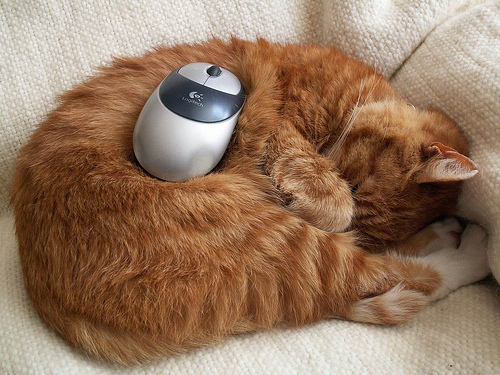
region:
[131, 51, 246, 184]
Computer mouse on cat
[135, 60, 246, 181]
Gray and black mouse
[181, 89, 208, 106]
Writing on a mouse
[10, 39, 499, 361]
Cat lying on couch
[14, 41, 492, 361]
Brown cat on couch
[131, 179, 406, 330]
Stripes on body's cat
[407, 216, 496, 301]
White fur on cat's legs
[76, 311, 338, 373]
Brown tail of a cat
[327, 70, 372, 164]
White whiskers on cat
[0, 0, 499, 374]
White couch with dots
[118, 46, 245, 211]
grey mouse on cat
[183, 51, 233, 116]
grey buttons on mouse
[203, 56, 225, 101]
black scroll wheel on mouse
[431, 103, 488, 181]
cat has orange ears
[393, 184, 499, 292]
cat has white paws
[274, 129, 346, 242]
cat has orange paws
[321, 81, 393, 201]
cat has long whiskers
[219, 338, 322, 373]
cat on white sofa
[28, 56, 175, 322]
cat has thick fur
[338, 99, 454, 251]
orange and brown face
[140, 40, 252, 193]
Computer mouse laying on a cat.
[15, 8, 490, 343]
Cat laying on the couch.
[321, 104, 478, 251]
A cat hiding its face.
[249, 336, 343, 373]
White cloth on a couch.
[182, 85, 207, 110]
Logo on the cat.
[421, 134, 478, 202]
The ear of a cat.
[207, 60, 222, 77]
Scroll bar on the mouse.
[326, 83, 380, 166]
Whiskers of a cat.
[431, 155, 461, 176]
Hair in a cat's ear.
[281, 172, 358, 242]
Cat hiding its paw.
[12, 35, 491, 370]
a computer mouse sitting on top of a sleeping cat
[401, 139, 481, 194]
the ear of a cat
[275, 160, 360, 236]
a paw of a cat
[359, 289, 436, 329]
the tip of the tail of a cat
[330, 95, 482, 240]
a head of a cat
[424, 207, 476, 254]
a paw of a cat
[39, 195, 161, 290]
the fur of a cat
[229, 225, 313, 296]
the fur of a cat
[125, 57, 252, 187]
a grey and black computer mouse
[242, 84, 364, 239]
the front leg of a computer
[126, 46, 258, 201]
silver and black mouse on a cat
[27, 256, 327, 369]
orange cat fur against white blanket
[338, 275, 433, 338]
end of striped cat tail under leg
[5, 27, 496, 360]
orange cat laying on a white blanket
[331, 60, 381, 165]
long white whiskers on orange cat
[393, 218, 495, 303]
white feet on orange furry cat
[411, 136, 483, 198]
pointed orange ear on cat's head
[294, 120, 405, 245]
cat has head tucked in under paw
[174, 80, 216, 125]
white logitech logo on black trim of mouse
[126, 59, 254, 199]
black and silver computer mouse